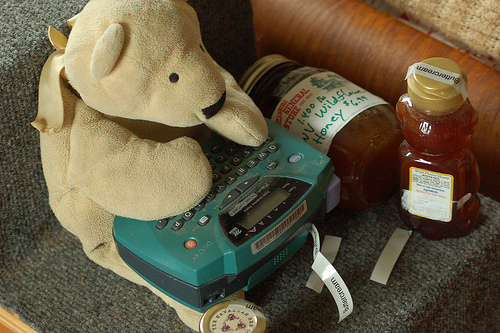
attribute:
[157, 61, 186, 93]
right eye — small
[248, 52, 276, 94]
lid — metal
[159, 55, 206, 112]
eye — black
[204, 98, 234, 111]
nose — black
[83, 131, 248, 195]
arm — brown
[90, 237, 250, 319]
leg — brown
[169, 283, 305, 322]
foot — brown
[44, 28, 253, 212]
bear — tan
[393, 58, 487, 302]
container — full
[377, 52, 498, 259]
honey — brown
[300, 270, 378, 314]
writing — black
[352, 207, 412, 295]
tag — white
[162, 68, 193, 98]
eye — round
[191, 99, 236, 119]
nose — brown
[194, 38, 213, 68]
eye — brown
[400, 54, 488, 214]
bottle — brown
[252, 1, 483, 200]
side — wooden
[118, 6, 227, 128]
face — happy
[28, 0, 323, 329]
bear — stuffed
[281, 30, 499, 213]
honey — different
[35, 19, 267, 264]
bear — stuffed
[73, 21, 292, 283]
bear — labeling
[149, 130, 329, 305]
label maker — dusty